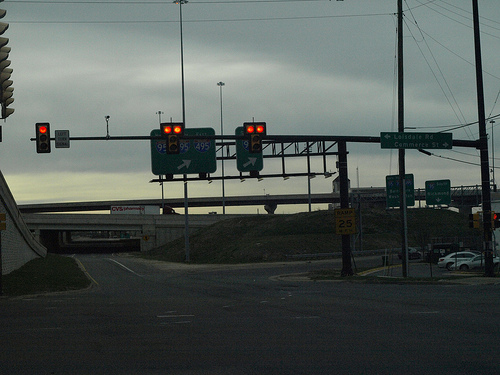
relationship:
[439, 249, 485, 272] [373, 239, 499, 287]
cars parked in a lot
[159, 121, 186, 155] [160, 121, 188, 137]
traffic light has double lights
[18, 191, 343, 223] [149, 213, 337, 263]
overpass has a hill gradiant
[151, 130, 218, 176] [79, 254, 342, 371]
information sign above street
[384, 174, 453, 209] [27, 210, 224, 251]
traffic signs on road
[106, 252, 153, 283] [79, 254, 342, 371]
traffic lines painted on street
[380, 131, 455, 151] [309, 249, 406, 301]
street sign on street corner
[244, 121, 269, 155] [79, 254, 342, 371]
traffic lights above street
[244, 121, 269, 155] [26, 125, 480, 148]
traffic lights mounted on a street pole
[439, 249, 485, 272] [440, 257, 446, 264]
car has a tail light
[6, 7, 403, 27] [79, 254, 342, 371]
electrical wires above street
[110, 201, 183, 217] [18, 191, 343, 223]
tractor trailer on overpass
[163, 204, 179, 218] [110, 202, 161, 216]
cab pulling a trailer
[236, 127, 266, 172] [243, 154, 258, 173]
traffi sign with an arrow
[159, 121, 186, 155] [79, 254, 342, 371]
traffic light over street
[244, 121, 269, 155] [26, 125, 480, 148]
traffic lights on a street pole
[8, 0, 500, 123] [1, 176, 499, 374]
sky above traffic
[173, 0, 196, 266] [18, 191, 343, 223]
street light pole above overpass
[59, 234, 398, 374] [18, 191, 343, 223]
street below overpass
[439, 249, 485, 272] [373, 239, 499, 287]
car parked in lot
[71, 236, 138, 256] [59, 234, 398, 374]
shadow on street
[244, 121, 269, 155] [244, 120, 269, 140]
stop traffic lights are red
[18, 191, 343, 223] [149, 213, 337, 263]
overpass has a slope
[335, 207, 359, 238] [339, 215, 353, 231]
yellow sign has speed limit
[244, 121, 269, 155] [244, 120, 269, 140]
traffic lights are red for stop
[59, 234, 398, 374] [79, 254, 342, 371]
no cars on street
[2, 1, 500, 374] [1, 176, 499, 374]
early morning in streets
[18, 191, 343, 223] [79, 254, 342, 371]
overpass above street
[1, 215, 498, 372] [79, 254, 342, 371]
no traffic on street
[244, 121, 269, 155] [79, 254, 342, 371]
traffic lights over street